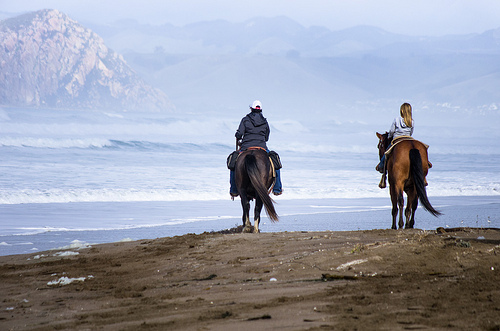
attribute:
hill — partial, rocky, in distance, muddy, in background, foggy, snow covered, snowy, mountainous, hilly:
[2, 7, 169, 116]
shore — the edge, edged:
[0, 224, 499, 330]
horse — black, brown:
[231, 149, 282, 234]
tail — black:
[244, 154, 279, 219]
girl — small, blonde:
[388, 99, 417, 141]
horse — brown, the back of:
[374, 130, 430, 232]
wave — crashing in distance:
[3, 135, 499, 162]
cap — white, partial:
[250, 101, 264, 112]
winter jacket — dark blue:
[235, 113, 274, 149]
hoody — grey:
[387, 117, 418, 138]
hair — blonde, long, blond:
[397, 103, 415, 125]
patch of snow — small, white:
[47, 270, 95, 286]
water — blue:
[1, 106, 499, 245]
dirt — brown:
[1, 224, 494, 330]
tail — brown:
[408, 145, 441, 216]